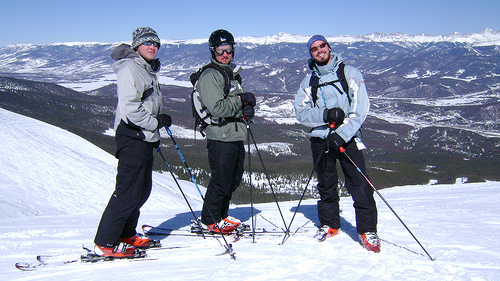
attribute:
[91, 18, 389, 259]
men — posing, clothed, standing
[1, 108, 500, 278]
slope — snow covered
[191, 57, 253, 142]
jacket — green, gray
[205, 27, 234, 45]
helmet — black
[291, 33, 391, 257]
man — smiling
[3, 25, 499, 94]
mountains — snowy, range, snow covered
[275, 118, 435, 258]
ski poles — black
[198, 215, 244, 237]
ski boots — red, orange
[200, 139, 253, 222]
pants — black, dark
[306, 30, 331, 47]
beanie — blue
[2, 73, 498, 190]
valley — covered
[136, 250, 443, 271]
snow — flat, white